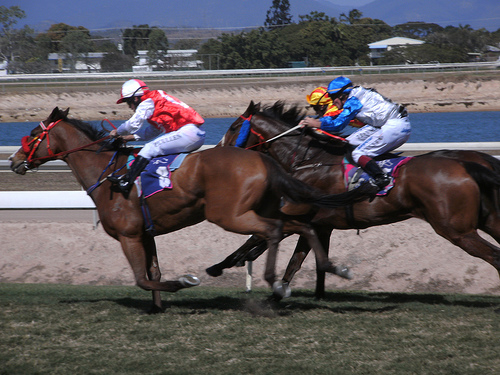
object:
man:
[106, 79, 205, 197]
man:
[304, 84, 364, 141]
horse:
[7, 103, 380, 314]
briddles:
[19, 118, 116, 163]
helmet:
[116, 78, 150, 104]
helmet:
[326, 75, 353, 95]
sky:
[0, 1, 499, 32]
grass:
[1, 279, 500, 374]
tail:
[260, 150, 378, 209]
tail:
[440, 147, 500, 204]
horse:
[213, 97, 498, 299]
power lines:
[0, 16, 500, 49]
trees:
[0, 0, 499, 74]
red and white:
[108, 79, 206, 160]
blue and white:
[314, 76, 412, 164]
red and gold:
[306, 86, 364, 128]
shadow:
[56, 295, 244, 315]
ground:
[0, 275, 499, 375]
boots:
[106, 155, 150, 193]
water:
[0, 109, 499, 141]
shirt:
[110, 87, 204, 137]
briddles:
[236, 114, 305, 155]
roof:
[137, 49, 198, 55]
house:
[131, 45, 203, 72]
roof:
[365, 36, 426, 46]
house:
[366, 37, 425, 64]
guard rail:
[0, 59, 500, 81]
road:
[0, 62, 500, 85]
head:
[7, 106, 74, 176]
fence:
[1, 138, 500, 222]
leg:
[223, 231, 265, 271]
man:
[298, 76, 413, 192]